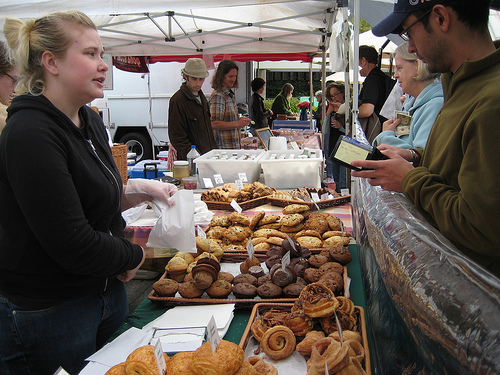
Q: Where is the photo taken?
A: A market.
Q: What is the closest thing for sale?
A: Rolls.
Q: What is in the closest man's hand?
A: His wallet.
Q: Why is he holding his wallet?
A: He is paying.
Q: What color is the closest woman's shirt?
A: Black.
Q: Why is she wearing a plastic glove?
A: Food safety.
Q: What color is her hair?
A: Blonde.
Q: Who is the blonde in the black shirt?
A: A merchant.